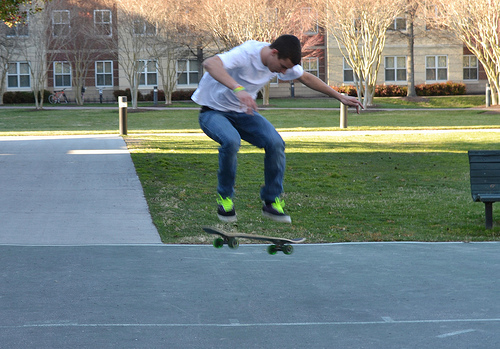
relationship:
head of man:
[262, 33, 307, 72] [190, 34, 365, 224]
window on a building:
[383, 54, 407, 82] [114, 2, 499, 88]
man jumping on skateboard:
[190, 34, 365, 224] [195, 212, 309, 260]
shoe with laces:
[215, 193, 237, 221] [216, 193, 235, 213]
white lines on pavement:
[7, 309, 498, 329] [4, 239, 498, 344]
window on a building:
[424, 54, 451, 83] [2, 0, 497, 102]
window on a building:
[378, 54, 408, 81] [2, 0, 497, 102]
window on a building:
[134, 57, 164, 88] [2, 0, 497, 102]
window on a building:
[5, 60, 35, 91] [2, 0, 497, 102]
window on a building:
[171, 54, 206, 87] [2, 0, 497, 102]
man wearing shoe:
[190, 34, 365, 224] [263, 200, 300, 225]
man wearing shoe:
[190, 34, 365, 224] [217, 189, 239, 222]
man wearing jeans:
[190, 34, 365, 224] [197, 105, 287, 197]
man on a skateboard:
[178, 34, 369, 225] [204, 222, 309, 260]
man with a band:
[190, 34, 365, 224] [228, 83, 247, 94]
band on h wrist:
[228, 83, 247, 94] [337, 88, 347, 106]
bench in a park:
[465, 144, 498, 226] [0, 0, 497, 348]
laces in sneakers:
[216, 193, 235, 213] [191, 181, 329, 229]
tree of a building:
[417, 0, 499, 105] [0, 0, 47, 105]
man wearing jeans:
[190, 34, 365, 224] [199, 106, 284, 201]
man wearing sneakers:
[190, 34, 365, 224] [213, 191, 295, 226]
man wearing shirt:
[190, 34, 365, 224] [190, 40, 304, 113]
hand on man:
[237, 85, 265, 117] [190, 34, 365, 224]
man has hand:
[190, 34, 365, 224] [337, 93, 364, 114]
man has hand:
[190, 34, 365, 224] [234, 91, 259, 112]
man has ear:
[190, 34, 365, 224] [270, 47, 278, 55]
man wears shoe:
[190, 34, 365, 224] [260, 196, 292, 224]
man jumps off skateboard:
[190, 34, 365, 224] [203, 224, 308, 256]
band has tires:
[232, 85, 246, 94] [208, 230, 245, 254]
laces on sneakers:
[216, 193, 235, 213] [209, 193, 238, 220]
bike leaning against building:
[43, 85, 77, 105] [0, 0, 496, 103]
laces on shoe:
[215, 194, 235, 214] [215, 193, 237, 221]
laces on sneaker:
[270, 194, 286, 214] [258, 190, 289, 220]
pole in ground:
[97, 86, 141, 143] [2, 93, 495, 347]